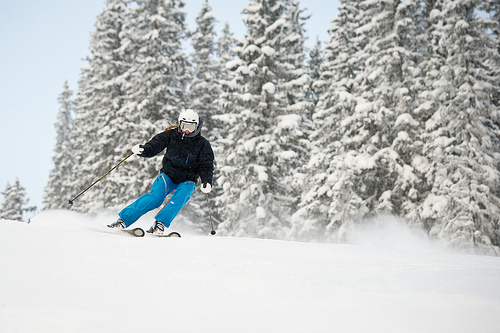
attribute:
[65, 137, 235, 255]
ski poles — Black 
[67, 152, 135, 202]
stick — skating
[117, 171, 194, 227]
pants — blue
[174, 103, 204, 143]
helmet — White 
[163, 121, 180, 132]
hair — blond 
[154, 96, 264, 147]
helmet — white 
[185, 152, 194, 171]
line — small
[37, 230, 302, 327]
snow — white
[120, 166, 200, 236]
ski pants — Blue 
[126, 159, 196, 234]
pants — blue 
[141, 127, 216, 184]
jacket — dark , black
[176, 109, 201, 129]
helmet — white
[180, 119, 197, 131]
goggles — white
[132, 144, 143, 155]
gloves — White 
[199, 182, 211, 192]
gloves — White 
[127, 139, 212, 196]
gloves — white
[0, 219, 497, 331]
snowy ground — Fluffy , white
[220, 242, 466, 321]
snow — white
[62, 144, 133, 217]
poles — ski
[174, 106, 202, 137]
face — skiers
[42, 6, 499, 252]
trees — snow covered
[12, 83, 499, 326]
game — skating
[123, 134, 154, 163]
gloves — white